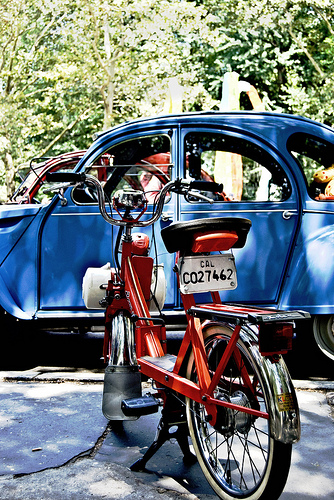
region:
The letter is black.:
[197, 257, 206, 269]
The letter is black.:
[203, 258, 210, 267]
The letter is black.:
[208, 257, 216, 267]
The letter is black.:
[181, 269, 190, 285]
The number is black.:
[188, 269, 198, 285]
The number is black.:
[197, 267, 205, 283]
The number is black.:
[203, 267, 213, 283]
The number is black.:
[210, 265, 219, 283]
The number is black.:
[219, 263, 228, 284]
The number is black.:
[225, 265, 234, 282]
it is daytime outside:
[3, 1, 332, 496]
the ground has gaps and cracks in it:
[6, 381, 332, 494]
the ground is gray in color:
[9, 380, 332, 497]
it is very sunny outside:
[1, 5, 332, 489]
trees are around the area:
[7, 4, 328, 206]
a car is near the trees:
[8, 109, 329, 350]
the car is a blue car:
[2, 114, 326, 352]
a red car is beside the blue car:
[9, 153, 229, 211]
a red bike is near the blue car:
[45, 162, 302, 498]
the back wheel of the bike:
[184, 317, 286, 496]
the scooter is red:
[132, 291, 152, 329]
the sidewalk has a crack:
[81, 432, 112, 458]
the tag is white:
[192, 265, 224, 282]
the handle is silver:
[91, 192, 108, 210]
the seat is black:
[183, 221, 210, 226]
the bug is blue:
[53, 229, 73, 248]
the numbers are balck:
[188, 271, 228, 280]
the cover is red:
[201, 239, 232, 248]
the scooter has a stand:
[140, 428, 213, 471]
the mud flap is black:
[110, 378, 131, 394]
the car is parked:
[1, 128, 326, 315]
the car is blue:
[0, 150, 328, 332]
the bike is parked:
[37, 152, 310, 469]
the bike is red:
[46, 125, 302, 485]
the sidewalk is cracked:
[10, 379, 189, 496]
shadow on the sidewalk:
[10, 366, 185, 496]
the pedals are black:
[106, 379, 164, 444]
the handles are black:
[184, 168, 233, 216]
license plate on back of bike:
[173, 248, 239, 292]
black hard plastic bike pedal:
[116, 394, 158, 416]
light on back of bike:
[255, 321, 295, 349]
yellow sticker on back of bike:
[277, 387, 300, 412]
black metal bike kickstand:
[124, 436, 194, 478]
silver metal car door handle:
[276, 201, 297, 222]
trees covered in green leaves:
[207, 1, 332, 78]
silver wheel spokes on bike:
[217, 438, 260, 482]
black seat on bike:
[155, 208, 257, 249]